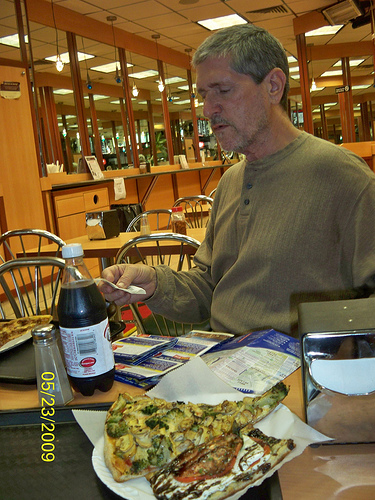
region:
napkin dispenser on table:
[89, 203, 131, 245]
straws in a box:
[42, 145, 82, 197]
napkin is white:
[309, 354, 372, 382]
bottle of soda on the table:
[37, 256, 135, 402]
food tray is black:
[14, 393, 279, 498]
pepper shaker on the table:
[37, 332, 90, 416]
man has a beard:
[197, 112, 303, 174]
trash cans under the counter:
[59, 186, 115, 222]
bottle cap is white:
[58, 236, 91, 260]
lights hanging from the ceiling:
[38, 34, 177, 100]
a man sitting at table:
[96, 11, 373, 347]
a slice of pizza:
[96, 387, 294, 480]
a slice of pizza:
[144, 418, 292, 495]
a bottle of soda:
[51, 240, 116, 394]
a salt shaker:
[23, 322, 72, 402]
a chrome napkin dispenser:
[292, 294, 373, 446]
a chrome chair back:
[2, 253, 97, 324]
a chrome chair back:
[105, 229, 208, 332]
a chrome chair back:
[128, 207, 186, 265]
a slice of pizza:
[140, 390, 172, 438]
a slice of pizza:
[145, 382, 218, 472]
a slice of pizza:
[106, 306, 229, 498]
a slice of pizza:
[163, 388, 240, 487]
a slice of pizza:
[155, 404, 203, 485]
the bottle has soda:
[48, 268, 129, 402]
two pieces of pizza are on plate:
[109, 393, 292, 498]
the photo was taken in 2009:
[33, 373, 62, 466]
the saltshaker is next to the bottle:
[29, 319, 79, 406]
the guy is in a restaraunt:
[0, 0, 374, 497]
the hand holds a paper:
[97, 255, 171, 311]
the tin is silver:
[298, 309, 373, 450]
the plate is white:
[93, 460, 135, 498]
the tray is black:
[10, 432, 81, 498]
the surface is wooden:
[302, 459, 374, 498]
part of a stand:
[172, 183, 180, 193]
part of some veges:
[130, 416, 164, 454]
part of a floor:
[299, 463, 333, 492]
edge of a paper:
[292, 430, 323, 453]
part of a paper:
[192, 374, 214, 397]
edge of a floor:
[321, 452, 337, 463]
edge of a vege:
[250, 413, 262, 424]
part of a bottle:
[85, 373, 107, 385]